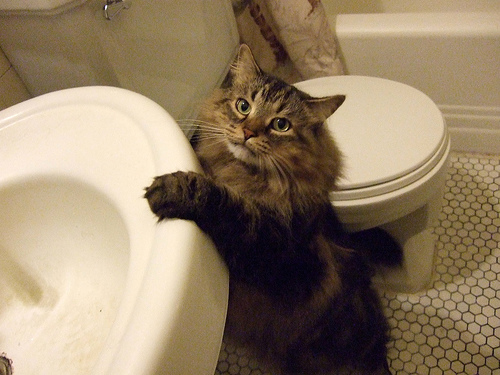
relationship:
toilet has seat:
[1, 0, 450, 294] [287, 75, 450, 203]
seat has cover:
[287, 75, 450, 203] [288, 76, 444, 191]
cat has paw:
[145, 43, 391, 374] [148, 170, 274, 284]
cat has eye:
[145, 43, 391, 374] [236, 97, 251, 117]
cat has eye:
[145, 43, 391, 374] [270, 117, 293, 132]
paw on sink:
[148, 170, 274, 284] [1, 85, 230, 375]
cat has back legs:
[145, 43, 391, 374] [267, 311, 393, 375]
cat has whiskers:
[145, 43, 391, 374] [182, 117, 300, 195]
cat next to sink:
[145, 43, 391, 374] [1, 85, 230, 375]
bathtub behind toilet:
[328, 0, 499, 155] [1, 0, 450, 294]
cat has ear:
[145, 43, 391, 374] [233, 44, 264, 89]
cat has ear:
[145, 43, 391, 374] [306, 94, 347, 126]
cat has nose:
[145, 43, 391, 374] [241, 125, 258, 140]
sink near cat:
[1, 85, 230, 375] [145, 43, 391, 374]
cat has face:
[145, 43, 391, 374] [224, 89, 298, 164]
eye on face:
[236, 97, 251, 117] [224, 89, 298, 164]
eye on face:
[270, 117, 293, 132] [224, 89, 298, 164]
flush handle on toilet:
[103, 0, 133, 21] [1, 0, 450, 294]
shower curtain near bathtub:
[233, 0, 349, 85] [328, 0, 499, 155]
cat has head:
[145, 43, 391, 374] [195, 44, 346, 174]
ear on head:
[233, 44, 264, 89] [195, 44, 346, 174]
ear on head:
[306, 94, 347, 126] [195, 44, 346, 174]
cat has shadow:
[145, 43, 391, 374] [383, 297, 499, 375]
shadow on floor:
[383, 297, 499, 375] [216, 125, 500, 374]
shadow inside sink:
[1, 243, 45, 308] [1, 85, 230, 375]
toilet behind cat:
[1, 0, 450, 294] [145, 43, 391, 374]